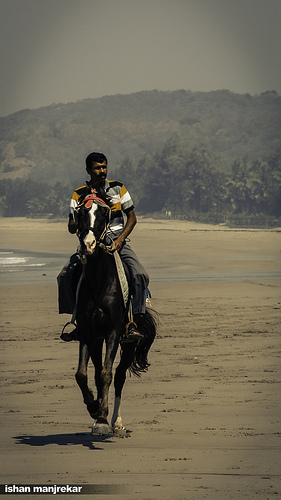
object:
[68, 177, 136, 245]
shirt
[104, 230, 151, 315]
pants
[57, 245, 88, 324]
pants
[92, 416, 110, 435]
hoof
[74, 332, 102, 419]
leg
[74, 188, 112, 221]
headdress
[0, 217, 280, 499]
beach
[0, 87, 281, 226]
forest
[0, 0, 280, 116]
sky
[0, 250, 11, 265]
water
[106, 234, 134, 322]
blanket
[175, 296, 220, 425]
ground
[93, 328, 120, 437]
leg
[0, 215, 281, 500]
dirt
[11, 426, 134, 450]
shadow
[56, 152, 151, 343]
man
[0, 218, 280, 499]
sand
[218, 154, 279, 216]
bush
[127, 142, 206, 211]
bush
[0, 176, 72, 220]
bush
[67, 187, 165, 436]
horse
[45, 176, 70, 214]
trees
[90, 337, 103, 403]
leg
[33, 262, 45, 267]
water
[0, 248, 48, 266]
sand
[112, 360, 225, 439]
tracks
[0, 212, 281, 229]
edge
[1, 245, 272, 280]
sand line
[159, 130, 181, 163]
tree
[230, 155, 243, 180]
tree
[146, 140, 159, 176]
tree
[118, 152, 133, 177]
tree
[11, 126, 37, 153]
tree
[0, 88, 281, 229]
mountain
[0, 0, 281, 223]
background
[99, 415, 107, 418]
edge